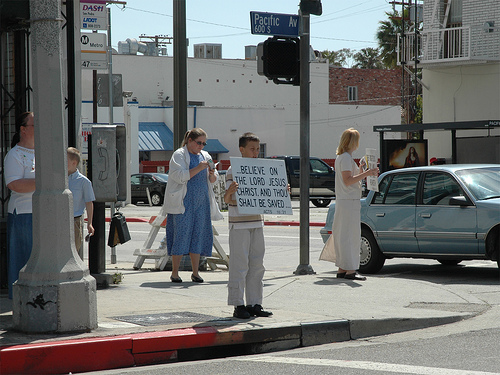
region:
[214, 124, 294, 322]
boy holding religious sign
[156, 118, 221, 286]
one woman wearing blue dress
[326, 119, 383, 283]
blonde woman holding sign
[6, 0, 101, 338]
one light colored metal pole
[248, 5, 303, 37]
one green and white street sign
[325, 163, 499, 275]
one blue sedan on street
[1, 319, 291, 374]
one red painted section of curb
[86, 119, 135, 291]
one silver metal phone booth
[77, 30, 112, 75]
one Metro station sign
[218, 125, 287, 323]
boy wearing tan colored pants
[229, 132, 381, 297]
Two people are holding signs.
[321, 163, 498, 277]
A blue car is going by.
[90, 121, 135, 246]
The phone booth has a book hanging from it.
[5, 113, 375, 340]
Five people are on the sidewalk.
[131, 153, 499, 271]
three vehicles are in the background.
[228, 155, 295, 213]
The sign is religious in nature.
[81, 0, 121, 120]
Transportation sign below top sign.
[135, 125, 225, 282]
A safety barrier is behind the woman.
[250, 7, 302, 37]
The sign is for Pacific Av.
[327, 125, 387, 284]
A woman in a white dress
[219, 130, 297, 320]
A boy holding a sign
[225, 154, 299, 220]
A white sign with black letters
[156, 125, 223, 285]
A woman in a blue dress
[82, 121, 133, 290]
A pay phone mounted to the sidewalk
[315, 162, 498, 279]
A light blue four door sedan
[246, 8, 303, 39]
A blue street sign with white letters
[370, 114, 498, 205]
A bus stop next to the street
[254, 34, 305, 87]
A walk/don't walk signal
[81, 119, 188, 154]
A blue canopy in the background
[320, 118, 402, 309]
A Woman Holding a Sign on a Street Corner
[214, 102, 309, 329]
A Boy Holding a Sign on a Street Corner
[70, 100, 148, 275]
A Coin Operated Phone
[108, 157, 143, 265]
A Black Phone Book Hanging From a Pay Phone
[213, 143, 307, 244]
A Sign With a Religious Statement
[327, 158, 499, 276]
A Blue Passenger Car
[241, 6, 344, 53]
A Blue Street Sign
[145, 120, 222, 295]
A Middle Aged Woman In a Blue Dress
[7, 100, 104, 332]
Two Individuals Covered By A Concrete Pole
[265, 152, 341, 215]
A Black Pick Up Truck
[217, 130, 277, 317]
Boy standing on a corner holding a religious sign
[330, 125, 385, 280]
Woman standing on a corner holding a sign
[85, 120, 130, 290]
Payphone booth on street corner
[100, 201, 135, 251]
Phone book attached to payphone booth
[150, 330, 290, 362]
Water drain in street curb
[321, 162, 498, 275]
Blue automobile on the street near the corner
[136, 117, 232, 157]
Building awning for a local business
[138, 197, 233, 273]
Construction sign to protect pedestrians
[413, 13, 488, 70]
Metal balcony on side of building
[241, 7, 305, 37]
Street sign that provides name of street